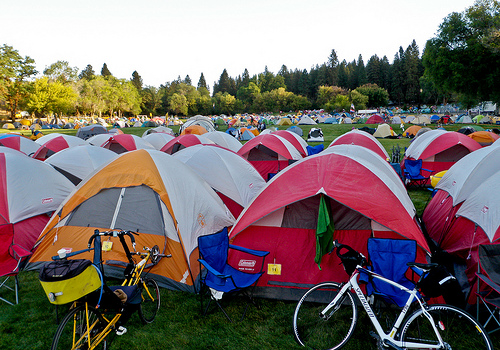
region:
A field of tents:
[1, 98, 498, 308]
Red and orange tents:
[17, 127, 431, 318]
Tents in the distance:
[100, 98, 453, 132]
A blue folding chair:
[188, 228, 270, 323]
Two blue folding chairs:
[189, 216, 441, 304]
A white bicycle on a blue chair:
[266, 221, 492, 349]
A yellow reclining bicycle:
[39, 223, 164, 349]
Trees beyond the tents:
[8, 41, 497, 111]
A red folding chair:
[0, 214, 50, 296]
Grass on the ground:
[8, 263, 454, 348]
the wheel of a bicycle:
[288, 278, 361, 348]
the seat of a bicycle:
[404, 257, 441, 274]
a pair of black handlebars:
[324, 235, 380, 270]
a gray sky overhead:
[0, 0, 499, 104]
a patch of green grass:
[1, 267, 499, 348]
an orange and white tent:
[18, 145, 239, 298]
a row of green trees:
[0, 0, 499, 122]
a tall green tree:
[0, 43, 39, 140]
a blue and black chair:
[190, 221, 275, 323]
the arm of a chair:
[190, 253, 234, 290]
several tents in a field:
[16, 74, 490, 289]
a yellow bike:
[87, 237, 161, 332]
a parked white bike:
[299, 249, 446, 332]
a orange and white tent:
[91, 167, 191, 227]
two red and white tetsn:
[246, 127, 302, 171]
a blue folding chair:
[192, 236, 266, 311]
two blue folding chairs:
[180, 242, 430, 295]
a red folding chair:
[0, 212, 35, 302]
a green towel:
[313, 191, 339, 275]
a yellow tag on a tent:
[266, 254, 288, 279]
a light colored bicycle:
[289, 243, 494, 349]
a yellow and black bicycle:
[47, 228, 162, 348]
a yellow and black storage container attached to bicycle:
[40, 258, 103, 309]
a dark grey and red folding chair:
[472, 239, 499, 337]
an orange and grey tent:
[24, 148, 236, 292]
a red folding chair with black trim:
[2, 220, 32, 308]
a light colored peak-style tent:
[372, 120, 397, 144]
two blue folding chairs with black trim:
[194, 225, 428, 320]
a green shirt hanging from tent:
[311, 195, 337, 270]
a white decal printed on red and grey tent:
[233, 254, 258, 276]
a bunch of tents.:
[3, 103, 497, 309]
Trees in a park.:
[0, 3, 498, 125]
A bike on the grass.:
[291, 237, 495, 349]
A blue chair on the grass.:
[197, 225, 269, 322]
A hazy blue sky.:
[1, 0, 496, 97]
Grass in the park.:
[3, 120, 498, 347]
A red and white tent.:
[223, 143, 430, 310]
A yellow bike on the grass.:
[38, 228, 171, 348]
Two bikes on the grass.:
[38, 229, 491, 348]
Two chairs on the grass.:
[196, 226, 433, 339]